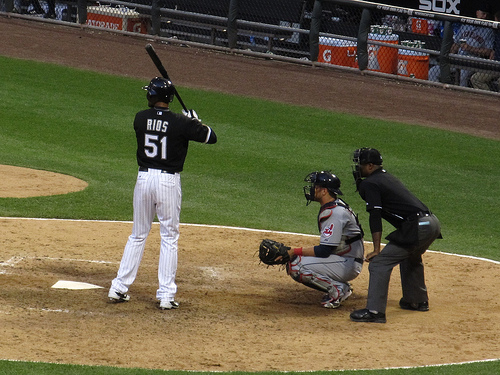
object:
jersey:
[132, 105, 210, 173]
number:
[144, 133, 168, 160]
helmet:
[139, 77, 175, 108]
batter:
[106, 76, 217, 310]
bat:
[145, 43, 189, 114]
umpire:
[350, 147, 442, 324]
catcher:
[259, 171, 364, 309]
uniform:
[285, 198, 364, 301]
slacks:
[366, 215, 439, 314]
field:
[0, 55, 500, 375]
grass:
[0, 57, 500, 265]